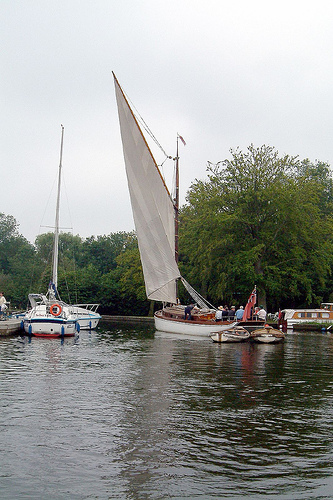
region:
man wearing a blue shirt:
[234, 304, 244, 321]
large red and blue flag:
[240, 285, 256, 322]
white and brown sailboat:
[110, 69, 266, 334]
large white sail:
[112, 71, 179, 306]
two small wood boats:
[208, 322, 284, 343]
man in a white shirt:
[255, 302, 266, 320]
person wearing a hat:
[215, 303, 224, 322]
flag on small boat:
[240, 281, 258, 324]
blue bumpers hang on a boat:
[18, 322, 85, 337]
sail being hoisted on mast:
[107, 69, 178, 297]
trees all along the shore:
[2, 142, 324, 311]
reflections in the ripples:
[204, 340, 329, 406]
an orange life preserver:
[50, 298, 58, 314]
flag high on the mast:
[175, 131, 185, 143]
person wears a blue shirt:
[233, 302, 241, 316]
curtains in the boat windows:
[295, 310, 326, 318]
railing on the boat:
[70, 302, 100, 317]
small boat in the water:
[253, 319, 286, 348]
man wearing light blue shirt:
[234, 302, 244, 318]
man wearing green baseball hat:
[257, 302, 268, 318]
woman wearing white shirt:
[1, 290, 8, 313]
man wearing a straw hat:
[212, 302, 223, 323]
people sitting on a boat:
[212, 298, 265, 323]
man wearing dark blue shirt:
[180, 298, 199, 318]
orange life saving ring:
[46, 299, 67, 317]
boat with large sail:
[104, 76, 243, 342]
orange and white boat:
[281, 301, 327, 334]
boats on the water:
[19, 273, 115, 361]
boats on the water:
[22, 268, 108, 370]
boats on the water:
[21, 271, 106, 341]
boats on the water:
[11, 268, 113, 350]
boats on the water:
[13, 270, 120, 348]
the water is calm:
[13, 348, 210, 435]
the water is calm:
[27, 356, 192, 435]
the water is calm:
[38, 360, 188, 406]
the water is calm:
[5, 334, 171, 414]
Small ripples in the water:
[22, 455, 48, 474]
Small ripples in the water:
[51, 440, 73, 470]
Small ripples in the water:
[86, 465, 125, 488]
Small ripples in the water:
[117, 432, 134, 450]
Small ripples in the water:
[123, 442, 152, 471]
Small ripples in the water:
[190, 461, 214, 484]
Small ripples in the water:
[211, 466, 243, 499]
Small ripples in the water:
[243, 458, 290, 484]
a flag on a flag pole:
[242, 285, 259, 317]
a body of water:
[2, 363, 313, 479]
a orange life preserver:
[48, 303, 62, 318]